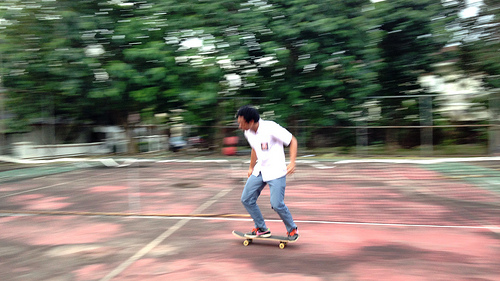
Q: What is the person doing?
A: Skateboarding.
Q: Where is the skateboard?
A: Under the guy.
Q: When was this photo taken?
A: Daytime.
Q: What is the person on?
A: A skateboard.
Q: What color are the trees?
A: Green.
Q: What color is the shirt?
A: White.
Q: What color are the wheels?
A: Yellow.